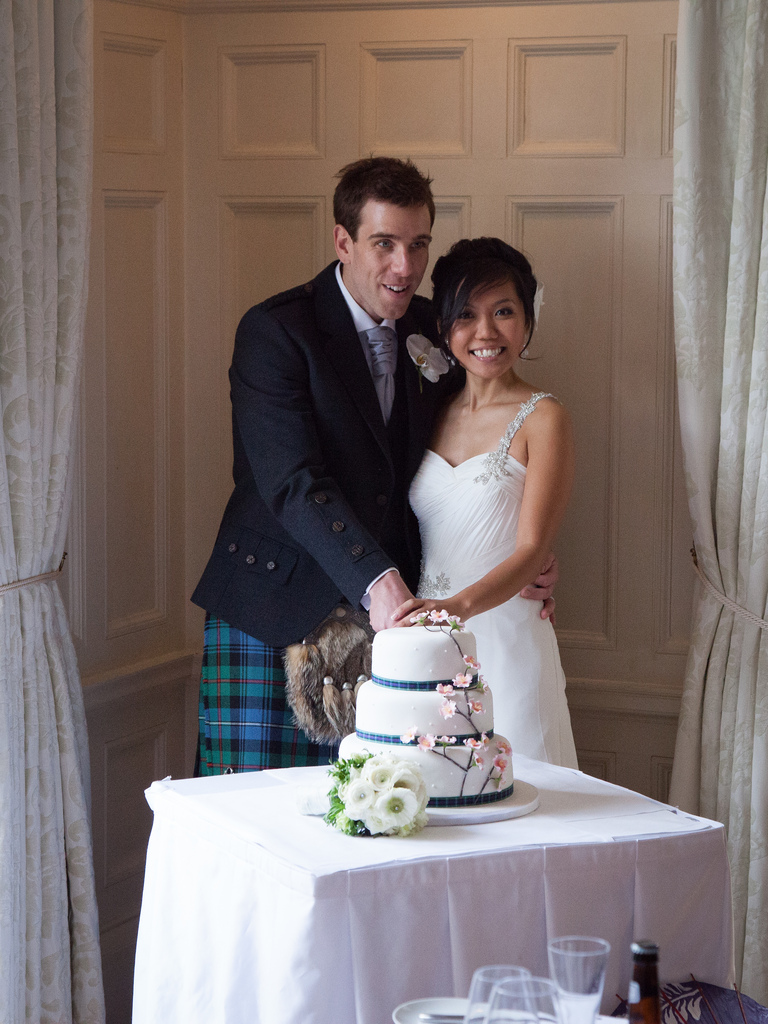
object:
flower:
[409, 610, 429, 629]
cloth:
[129, 744, 732, 1021]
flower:
[375, 786, 420, 829]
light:
[253, 882, 314, 937]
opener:
[629, 937, 661, 954]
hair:
[331, 148, 437, 246]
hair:
[429, 236, 545, 362]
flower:
[406, 332, 449, 382]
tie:
[363, 323, 398, 427]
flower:
[451, 673, 472, 689]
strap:
[496, 391, 562, 459]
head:
[430, 235, 545, 378]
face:
[447, 277, 531, 379]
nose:
[475, 312, 499, 339]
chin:
[466, 359, 513, 379]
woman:
[391, 237, 578, 766]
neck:
[458, 369, 517, 412]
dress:
[405, 388, 579, 774]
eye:
[494, 306, 514, 320]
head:
[333, 156, 437, 320]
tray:
[398, 778, 542, 828]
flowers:
[401, 610, 514, 796]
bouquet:
[323, 751, 432, 836]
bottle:
[626, 939, 661, 1022]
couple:
[189, 153, 579, 774]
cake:
[334, 607, 540, 826]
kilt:
[190, 611, 338, 780]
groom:
[187, 161, 557, 779]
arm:
[520, 551, 560, 623]